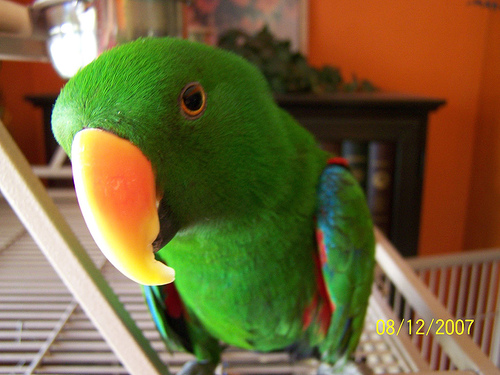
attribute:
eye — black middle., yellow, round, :
[172, 78, 209, 122]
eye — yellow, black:
[179, 81, 206, 118]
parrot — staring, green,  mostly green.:
[53, 38, 378, 374]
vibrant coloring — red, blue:
[303, 160, 342, 337]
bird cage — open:
[3, 129, 496, 374]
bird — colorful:
[43, 32, 378, 372]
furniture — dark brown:
[22, 89, 447, 324]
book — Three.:
[366, 139, 395, 246]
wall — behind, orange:
[313, 1, 499, 204]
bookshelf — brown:
[17, 91, 449, 327]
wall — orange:
[388, 31, 450, 61]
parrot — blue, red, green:
[10, 43, 496, 373]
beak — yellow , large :
[65, 132, 173, 286]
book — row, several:
[337, 136, 404, 220]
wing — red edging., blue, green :
[303, 163, 381, 373]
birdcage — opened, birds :
[15, 60, 484, 370]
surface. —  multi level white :
[4, 143, 465, 370]